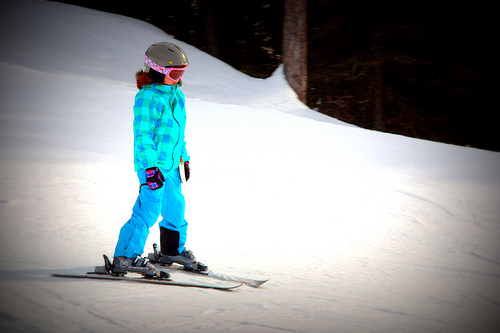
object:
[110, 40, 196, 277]
girl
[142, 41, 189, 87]
helmet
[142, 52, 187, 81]
goggles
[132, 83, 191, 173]
jacket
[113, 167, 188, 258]
pants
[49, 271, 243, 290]
ski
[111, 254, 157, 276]
boot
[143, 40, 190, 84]
head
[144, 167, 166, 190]
glove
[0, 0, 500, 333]
snow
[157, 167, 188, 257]
leg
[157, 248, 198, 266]
foot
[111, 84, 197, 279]
body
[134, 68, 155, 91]
hair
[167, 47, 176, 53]
hole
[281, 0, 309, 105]
tree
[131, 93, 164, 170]
sleeve